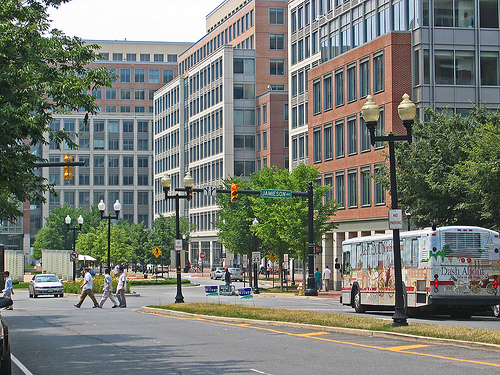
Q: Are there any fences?
A: No, there are no fences.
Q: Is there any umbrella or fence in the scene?
A: No, there are no fences or umbrellas.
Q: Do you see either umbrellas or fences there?
A: No, there are no fences or umbrellas.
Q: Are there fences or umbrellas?
A: No, there are no fences or umbrellas.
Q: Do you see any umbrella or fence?
A: No, there are no fences or umbrellas.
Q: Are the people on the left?
A: Yes, the people are on the left of the image.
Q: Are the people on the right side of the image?
A: No, the people are on the left of the image.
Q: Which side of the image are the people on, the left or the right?
A: The people are on the left of the image.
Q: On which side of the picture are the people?
A: The people are on the left of the image.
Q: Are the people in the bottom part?
A: Yes, the people are in the bottom of the image.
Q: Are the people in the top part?
A: No, the people are in the bottom of the image.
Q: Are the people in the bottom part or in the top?
A: The people are in the bottom of the image.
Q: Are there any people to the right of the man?
A: Yes, there are people to the right of the man.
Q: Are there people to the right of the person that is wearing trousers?
A: Yes, there are people to the right of the man.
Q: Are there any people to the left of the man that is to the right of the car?
A: No, the people are to the right of the man.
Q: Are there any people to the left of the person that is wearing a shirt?
A: No, the people are to the right of the man.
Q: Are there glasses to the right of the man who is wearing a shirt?
A: No, there are people to the right of the man.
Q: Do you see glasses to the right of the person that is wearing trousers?
A: No, there are people to the right of the man.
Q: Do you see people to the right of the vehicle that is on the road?
A: Yes, there are people to the right of the car.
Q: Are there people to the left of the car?
A: No, the people are to the right of the car.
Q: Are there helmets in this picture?
A: No, there are no helmets.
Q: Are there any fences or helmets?
A: No, there are no helmets or fences.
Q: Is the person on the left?
A: Yes, the person is on the left of the image.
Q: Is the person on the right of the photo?
A: No, the person is on the left of the image.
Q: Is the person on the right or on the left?
A: The person is on the left of the image.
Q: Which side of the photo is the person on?
A: The person is on the left of the image.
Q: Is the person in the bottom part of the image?
A: Yes, the person is in the bottom of the image.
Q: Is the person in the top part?
A: No, the person is in the bottom of the image.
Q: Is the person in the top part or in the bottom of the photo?
A: The person is in the bottom of the image.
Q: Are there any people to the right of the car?
A: Yes, there is a person to the right of the car.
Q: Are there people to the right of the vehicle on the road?
A: Yes, there is a person to the right of the car.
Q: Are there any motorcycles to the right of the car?
A: No, there is a person to the right of the car.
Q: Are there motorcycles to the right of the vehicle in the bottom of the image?
A: No, there is a person to the right of the car.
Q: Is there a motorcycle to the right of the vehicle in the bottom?
A: No, there is a person to the right of the car.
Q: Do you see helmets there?
A: No, there are no helmets.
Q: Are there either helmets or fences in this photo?
A: No, there are no helmets or fences.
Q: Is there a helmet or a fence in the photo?
A: No, there are no helmets or fences.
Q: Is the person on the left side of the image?
A: Yes, the person is on the left of the image.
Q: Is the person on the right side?
A: No, the person is on the left of the image.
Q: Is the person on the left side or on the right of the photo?
A: The person is on the left of the image.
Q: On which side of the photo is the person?
A: The person is on the left of the image.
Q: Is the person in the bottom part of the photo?
A: Yes, the person is in the bottom of the image.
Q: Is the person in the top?
A: No, the person is in the bottom of the image.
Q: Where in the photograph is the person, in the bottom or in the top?
A: The person is in the bottom of the image.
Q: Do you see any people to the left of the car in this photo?
A: Yes, there is a person to the left of the car.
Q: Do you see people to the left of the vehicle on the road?
A: Yes, there is a person to the left of the car.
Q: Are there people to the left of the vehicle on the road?
A: Yes, there is a person to the left of the car.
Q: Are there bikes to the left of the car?
A: No, there is a person to the left of the car.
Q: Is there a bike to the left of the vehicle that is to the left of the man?
A: No, there is a person to the left of the car.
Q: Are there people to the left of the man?
A: Yes, there is a person to the left of the man.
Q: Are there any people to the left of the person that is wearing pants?
A: Yes, there is a person to the left of the man.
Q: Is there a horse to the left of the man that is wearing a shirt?
A: No, there is a person to the left of the man.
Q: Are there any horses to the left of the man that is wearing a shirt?
A: No, there is a person to the left of the man.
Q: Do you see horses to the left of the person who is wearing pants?
A: No, there is a person to the left of the man.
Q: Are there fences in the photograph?
A: No, there are no fences.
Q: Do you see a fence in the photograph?
A: No, there are no fences.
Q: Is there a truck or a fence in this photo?
A: No, there are no fences or trucks.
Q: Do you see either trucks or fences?
A: No, there are no fences or trucks.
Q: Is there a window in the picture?
A: Yes, there is a window.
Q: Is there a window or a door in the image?
A: Yes, there is a window.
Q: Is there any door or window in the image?
A: Yes, there is a window.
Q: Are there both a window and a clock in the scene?
A: No, there is a window but no clocks.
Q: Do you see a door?
A: No, there are no doors.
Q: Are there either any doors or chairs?
A: No, there are no doors or chairs.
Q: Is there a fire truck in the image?
A: No, there are no fire trucks.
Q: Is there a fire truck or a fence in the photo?
A: No, there are no fire trucks or fences.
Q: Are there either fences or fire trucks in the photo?
A: No, there are no fire trucks or fences.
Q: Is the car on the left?
A: Yes, the car is on the left of the image.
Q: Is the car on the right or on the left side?
A: The car is on the left of the image.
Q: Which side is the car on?
A: The car is on the left of the image.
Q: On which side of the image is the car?
A: The car is on the left of the image.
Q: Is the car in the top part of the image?
A: No, the car is in the bottom of the image.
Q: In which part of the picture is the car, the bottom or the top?
A: The car is in the bottom of the image.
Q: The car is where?
A: The car is on the road.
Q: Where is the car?
A: The car is on the road.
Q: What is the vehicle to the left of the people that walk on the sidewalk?
A: The vehicle is a car.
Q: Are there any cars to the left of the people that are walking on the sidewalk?
A: Yes, there is a car to the left of the people.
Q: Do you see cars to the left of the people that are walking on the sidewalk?
A: Yes, there is a car to the left of the people.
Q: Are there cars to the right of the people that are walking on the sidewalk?
A: No, the car is to the left of the people.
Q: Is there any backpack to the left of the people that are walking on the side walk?
A: No, there is a car to the left of the people.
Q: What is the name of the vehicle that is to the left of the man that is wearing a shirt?
A: The vehicle is a car.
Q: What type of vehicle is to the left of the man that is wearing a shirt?
A: The vehicle is a car.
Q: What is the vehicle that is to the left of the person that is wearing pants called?
A: The vehicle is a car.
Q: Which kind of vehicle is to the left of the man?
A: The vehicle is a car.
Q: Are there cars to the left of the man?
A: Yes, there is a car to the left of the man.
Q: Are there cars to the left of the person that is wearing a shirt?
A: Yes, there is a car to the left of the man.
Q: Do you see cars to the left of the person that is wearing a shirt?
A: Yes, there is a car to the left of the man.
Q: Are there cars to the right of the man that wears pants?
A: No, the car is to the left of the man.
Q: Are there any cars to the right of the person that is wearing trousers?
A: No, the car is to the left of the man.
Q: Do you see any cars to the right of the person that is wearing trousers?
A: No, the car is to the left of the man.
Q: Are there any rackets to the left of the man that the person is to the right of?
A: No, there is a car to the left of the man.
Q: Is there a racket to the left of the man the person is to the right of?
A: No, there is a car to the left of the man.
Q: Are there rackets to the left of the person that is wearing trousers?
A: No, there is a car to the left of the man.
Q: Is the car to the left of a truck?
A: No, the car is to the left of a man.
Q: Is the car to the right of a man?
A: No, the car is to the left of a man.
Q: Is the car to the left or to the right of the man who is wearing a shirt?
A: The car is to the left of the man.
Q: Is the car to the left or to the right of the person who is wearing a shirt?
A: The car is to the left of the man.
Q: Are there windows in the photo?
A: Yes, there is a window.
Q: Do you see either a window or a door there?
A: Yes, there is a window.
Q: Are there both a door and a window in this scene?
A: No, there is a window but no doors.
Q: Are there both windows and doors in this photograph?
A: No, there is a window but no doors.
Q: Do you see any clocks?
A: No, there are no clocks.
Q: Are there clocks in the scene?
A: No, there are no clocks.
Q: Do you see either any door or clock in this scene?
A: No, there are no clocks or doors.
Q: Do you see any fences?
A: No, there are no fences.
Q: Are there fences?
A: No, there are no fences.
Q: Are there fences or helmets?
A: No, there are no fences or helmets.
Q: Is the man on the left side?
A: Yes, the man is on the left of the image.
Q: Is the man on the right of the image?
A: No, the man is on the left of the image.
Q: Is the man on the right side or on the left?
A: The man is on the left of the image.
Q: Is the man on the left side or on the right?
A: The man is on the left of the image.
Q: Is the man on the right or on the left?
A: The man is on the left of the image.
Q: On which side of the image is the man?
A: The man is on the left of the image.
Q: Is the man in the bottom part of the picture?
A: Yes, the man is in the bottom of the image.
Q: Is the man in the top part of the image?
A: No, the man is in the bottom of the image.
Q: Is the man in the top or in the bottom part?
A: The man is in the bottom of the image.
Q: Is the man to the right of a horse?
A: No, the man is to the right of a person.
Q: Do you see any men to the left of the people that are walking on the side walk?
A: Yes, there is a man to the left of the people.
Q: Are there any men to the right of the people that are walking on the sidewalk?
A: No, the man is to the left of the people.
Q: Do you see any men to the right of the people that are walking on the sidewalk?
A: No, the man is to the left of the people.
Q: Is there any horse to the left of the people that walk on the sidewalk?
A: No, there is a man to the left of the people.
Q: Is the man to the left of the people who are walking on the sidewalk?
A: Yes, the man is to the left of the people.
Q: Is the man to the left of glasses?
A: No, the man is to the left of the people.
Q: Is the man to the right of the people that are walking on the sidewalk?
A: No, the man is to the left of the people.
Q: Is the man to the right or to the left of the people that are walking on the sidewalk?
A: The man is to the left of the people.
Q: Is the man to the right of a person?
A: No, the man is to the left of a person.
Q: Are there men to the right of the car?
A: Yes, there is a man to the right of the car.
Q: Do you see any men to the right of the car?
A: Yes, there is a man to the right of the car.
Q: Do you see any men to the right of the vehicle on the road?
A: Yes, there is a man to the right of the car.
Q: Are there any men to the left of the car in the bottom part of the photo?
A: No, the man is to the right of the car.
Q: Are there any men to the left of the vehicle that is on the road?
A: No, the man is to the right of the car.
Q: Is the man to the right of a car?
A: Yes, the man is to the right of a car.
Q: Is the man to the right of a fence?
A: No, the man is to the right of a car.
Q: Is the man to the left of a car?
A: No, the man is to the right of a car.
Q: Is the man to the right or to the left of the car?
A: The man is to the right of the car.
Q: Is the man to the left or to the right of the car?
A: The man is to the right of the car.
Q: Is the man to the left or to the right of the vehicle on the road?
A: The man is to the right of the car.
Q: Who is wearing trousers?
A: The man is wearing trousers.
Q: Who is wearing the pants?
A: The man is wearing trousers.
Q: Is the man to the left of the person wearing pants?
A: Yes, the man is wearing pants.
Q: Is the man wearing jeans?
A: No, the man is wearing pants.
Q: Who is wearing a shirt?
A: The man is wearing a shirt.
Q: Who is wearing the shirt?
A: The man is wearing a shirt.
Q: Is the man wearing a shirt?
A: Yes, the man is wearing a shirt.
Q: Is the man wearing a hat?
A: No, the man is wearing a shirt.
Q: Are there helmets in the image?
A: No, there are no helmets.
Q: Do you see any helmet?
A: No, there are no helmets.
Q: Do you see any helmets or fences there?
A: No, there are no helmets or fences.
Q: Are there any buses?
A: Yes, there is a bus.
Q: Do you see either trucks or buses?
A: Yes, there is a bus.